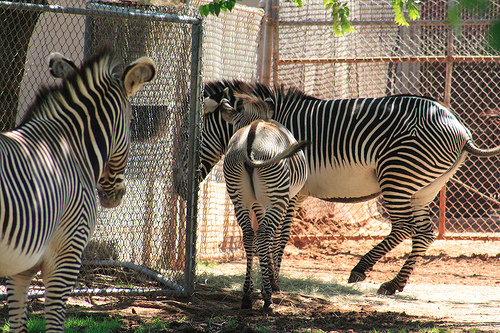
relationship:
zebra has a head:
[3, 38, 170, 333] [43, 40, 155, 212]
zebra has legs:
[3, 38, 170, 333] [343, 223, 446, 298]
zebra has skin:
[3, 38, 170, 333] [317, 109, 388, 150]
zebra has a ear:
[3, 38, 170, 333] [123, 51, 159, 98]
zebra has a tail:
[3, 38, 170, 333] [462, 137, 499, 159]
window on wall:
[135, 103, 169, 145] [161, 35, 183, 76]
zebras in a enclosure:
[7, 33, 495, 332] [157, 24, 333, 76]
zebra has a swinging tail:
[3, 38, 170, 333] [462, 137, 499, 159]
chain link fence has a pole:
[170, 15, 197, 90] [445, 52, 455, 103]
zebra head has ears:
[43, 40, 155, 212] [38, 48, 160, 97]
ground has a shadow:
[303, 299, 349, 323] [327, 300, 438, 330]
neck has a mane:
[256, 87, 301, 108] [80, 61, 115, 86]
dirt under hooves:
[281, 304, 346, 331] [344, 270, 401, 297]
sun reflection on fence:
[281, 36, 321, 55] [277, 30, 481, 73]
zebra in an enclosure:
[3, 38, 170, 333] [157, 24, 333, 76]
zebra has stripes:
[3, 38, 170, 333] [64, 109, 103, 131]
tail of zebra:
[462, 137, 499, 159] [3, 38, 170, 333]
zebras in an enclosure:
[7, 33, 495, 332] [157, 24, 333, 76]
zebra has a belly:
[3, 38, 170, 333] [312, 169, 373, 196]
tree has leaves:
[437, 3, 496, 46] [317, 2, 424, 39]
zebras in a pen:
[7, 33, 495, 332] [30, 20, 493, 181]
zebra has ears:
[3, 38, 170, 333] [38, 48, 160, 97]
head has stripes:
[43, 40, 155, 212] [64, 109, 103, 131]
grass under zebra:
[77, 316, 119, 332] [3, 38, 170, 333]